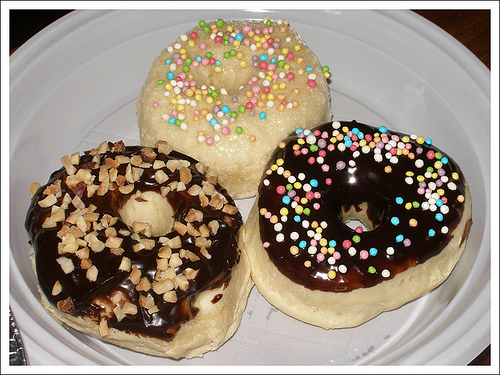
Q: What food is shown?
A: Doughnuts.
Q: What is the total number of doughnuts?
A: 3.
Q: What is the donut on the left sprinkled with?
A: Nuts.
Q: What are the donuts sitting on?
A: Plate.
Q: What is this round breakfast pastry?
A: Donut.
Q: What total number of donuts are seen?
A: Three.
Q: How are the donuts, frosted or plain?
A: Frosted.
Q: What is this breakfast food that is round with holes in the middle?
A: Donuts.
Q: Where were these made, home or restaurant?
A: Home.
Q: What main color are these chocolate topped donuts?
A: Brown.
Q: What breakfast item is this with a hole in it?
A: Donut.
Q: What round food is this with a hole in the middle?
A: Donut.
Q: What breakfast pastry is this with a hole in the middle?
A: Donut.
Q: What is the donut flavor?
A: Chocolate.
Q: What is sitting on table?
A: Donuts.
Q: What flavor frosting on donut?
A: Chocolate.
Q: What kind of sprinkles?
A: Colorful.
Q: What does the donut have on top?
A: Nuts.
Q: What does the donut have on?
A: Colorful sprinkles.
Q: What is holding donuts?
A: Plate.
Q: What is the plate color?
A: White.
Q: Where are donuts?
A: On a plate.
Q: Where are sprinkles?
A: On two donuts.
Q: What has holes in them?
A: The donuts.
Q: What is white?
A: The plate.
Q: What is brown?
A: Chocolate.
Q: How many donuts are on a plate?
A: Three.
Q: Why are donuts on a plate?
A: To be eaten.